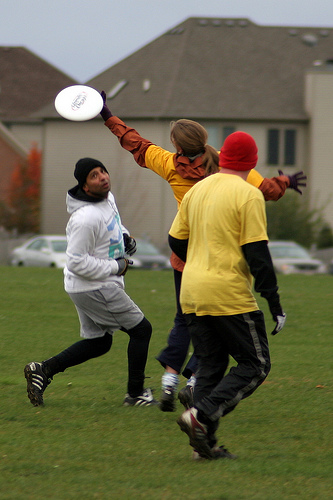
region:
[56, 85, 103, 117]
a white frisbee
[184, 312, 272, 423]
black sport pants with gray side stripe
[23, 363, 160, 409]
black and white sports cleats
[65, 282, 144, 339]
gray shorts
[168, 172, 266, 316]
light yellow short sleeve shirt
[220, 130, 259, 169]
a red tobaggin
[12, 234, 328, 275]
rows of cars next to field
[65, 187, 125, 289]
a white hoodie with blue print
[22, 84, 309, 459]
people playing with frisbee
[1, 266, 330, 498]
green grass of field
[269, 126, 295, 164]
a window of a home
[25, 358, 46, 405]
a black and white shoe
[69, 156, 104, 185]
a black cap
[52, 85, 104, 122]
a large white Frisbee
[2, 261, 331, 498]
a large section of green grass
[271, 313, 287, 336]
a black and white glove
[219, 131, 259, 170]
a red cap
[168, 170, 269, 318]
a man's yellow shirt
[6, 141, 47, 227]
part of a red and green tree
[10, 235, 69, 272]
part of a gray car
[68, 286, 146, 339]
a pair of gray shorts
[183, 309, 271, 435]
black sports pants with gry stripe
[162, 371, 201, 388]
pair of white socks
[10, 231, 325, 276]
cars parked beside field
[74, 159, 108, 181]
a black tobaggin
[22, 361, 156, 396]
black and white cleats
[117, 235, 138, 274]
gray and black gloves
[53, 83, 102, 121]
a white Frisbee disk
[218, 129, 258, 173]
a red knit cap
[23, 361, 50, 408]
black with white striped cleat shoes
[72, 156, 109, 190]
a black knit cap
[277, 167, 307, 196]
a black winter gloves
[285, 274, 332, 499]
a parks green field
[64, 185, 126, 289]
a white hood sweat shirt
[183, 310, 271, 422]
black warm up pants with a grey stripe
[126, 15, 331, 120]
the brown roof of a building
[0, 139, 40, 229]
a red flowering tree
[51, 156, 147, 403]
the guy in the black cap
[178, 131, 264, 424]
the guy in the red cap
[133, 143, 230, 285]
the woman catching the frisbee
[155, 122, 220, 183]
the woman in the pony tail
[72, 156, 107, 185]
the black cap on his head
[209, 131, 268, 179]
the red cap on his head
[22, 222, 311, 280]
the cars parked in the background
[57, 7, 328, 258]
the big house in the background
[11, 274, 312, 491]
the grass on the ground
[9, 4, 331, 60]
the sky behind the house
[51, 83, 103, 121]
white round frisbee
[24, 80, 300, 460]
three people playing frisbee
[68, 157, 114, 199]
man wearing a black hat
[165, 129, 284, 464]
man wearing a red hat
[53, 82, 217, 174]
woman catching a frisbee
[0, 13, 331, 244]
house with a brown roof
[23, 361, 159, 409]
black and white athletic shoes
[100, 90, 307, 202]
woman in a yellow shirt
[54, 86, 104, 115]
The frisbee is white.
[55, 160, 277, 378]
People are playing frisbee.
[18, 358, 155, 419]
The man is wearing black cleaks.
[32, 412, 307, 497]
The grass is green.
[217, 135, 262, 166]
A person is wearing red cap.